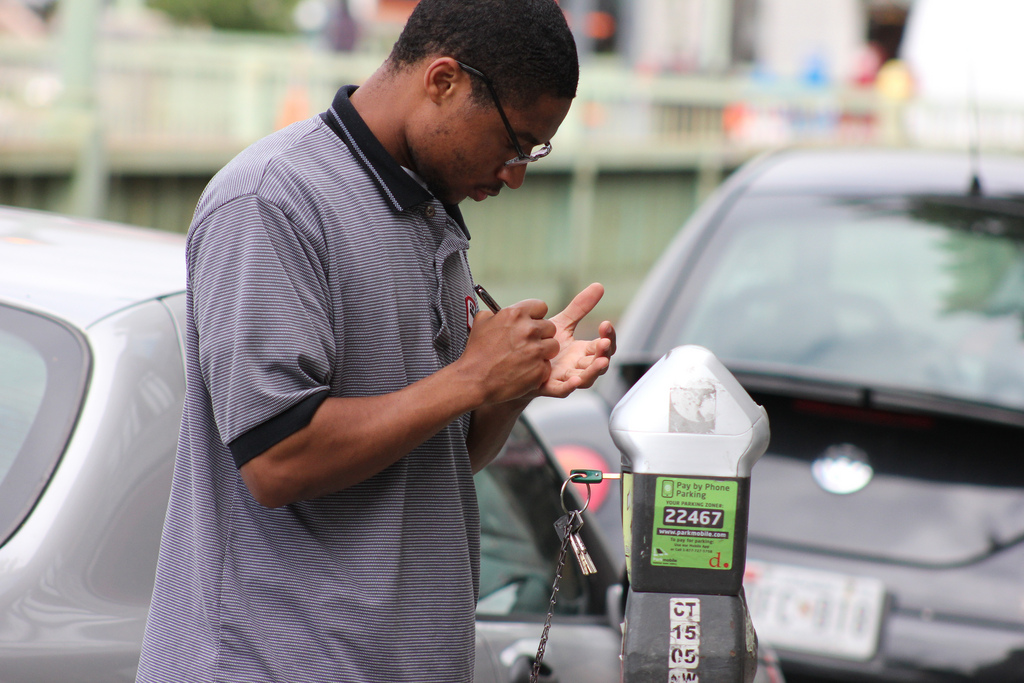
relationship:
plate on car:
[725, 549, 881, 647] [631, 156, 1012, 681]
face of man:
[435, 92, 575, 200] [156, 1, 627, 679]